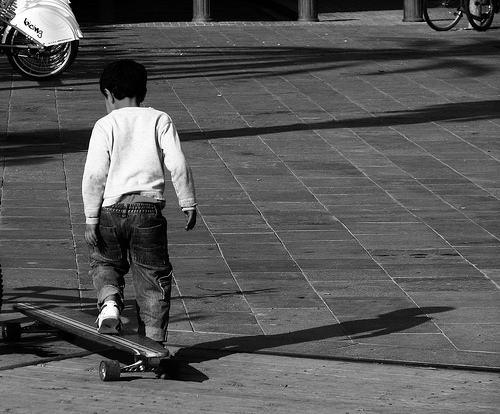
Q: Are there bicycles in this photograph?
A: Yes, there is a bicycle.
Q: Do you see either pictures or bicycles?
A: Yes, there is a bicycle.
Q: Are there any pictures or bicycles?
A: Yes, there is a bicycle.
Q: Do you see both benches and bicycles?
A: No, there is a bicycle but no benches.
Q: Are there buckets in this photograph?
A: No, there are no buckets.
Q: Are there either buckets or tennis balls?
A: No, there are no buckets or tennis balls.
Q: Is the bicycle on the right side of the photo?
A: Yes, the bicycle is on the right of the image.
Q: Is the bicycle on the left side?
A: No, the bicycle is on the right of the image.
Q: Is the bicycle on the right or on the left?
A: The bicycle is on the right of the image.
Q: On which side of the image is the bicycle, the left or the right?
A: The bicycle is on the right of the image.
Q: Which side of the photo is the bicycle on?
A: The bicycle is on the right of the image.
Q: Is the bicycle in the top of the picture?
A: Yes, the bicycle is in the top of the image.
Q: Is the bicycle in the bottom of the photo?
A: No, the bicycle is in the top of the image.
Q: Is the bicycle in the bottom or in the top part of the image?
A: The bicycle is in the top of the image.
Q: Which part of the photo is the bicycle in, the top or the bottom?
A: The bicycle is in the top of the image.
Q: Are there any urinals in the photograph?
A: No, there are no urinals.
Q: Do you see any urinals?
A: No, there are no urinals.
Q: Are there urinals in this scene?
A: No, there are no urinals.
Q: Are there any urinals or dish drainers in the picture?
A: No, there are no urinals or dish drainers.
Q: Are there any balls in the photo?
A: No, there are no balls.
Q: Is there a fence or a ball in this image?
A: No, there are no balls or fences.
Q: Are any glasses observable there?
A: No, there are no glasses.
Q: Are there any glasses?
A: No, there are no glasses.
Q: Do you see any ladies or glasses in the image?
A: No, there are no glasses or ladies.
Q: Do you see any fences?
A: No, there are no fences.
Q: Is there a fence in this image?
A: No, there are no fences.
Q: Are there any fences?
A: No, there are no fences.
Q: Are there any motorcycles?
A: Yes, there is a motorcycle.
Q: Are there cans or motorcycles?
A: Yes, there is a motorcycle.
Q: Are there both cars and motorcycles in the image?
A: No, there is a motorcycle but no cars.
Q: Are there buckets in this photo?
A: No, there are no buckets.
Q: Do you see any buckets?
A: No, there are no buckets.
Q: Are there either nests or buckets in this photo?
A: No, there are no buckets or nests.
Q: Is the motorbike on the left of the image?
A: Yes, the motorbike is on the left of the image.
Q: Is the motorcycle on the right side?
A: No, the motorcycle is on the left of the image.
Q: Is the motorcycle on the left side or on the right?
A: The motorcycle is on the left of the image.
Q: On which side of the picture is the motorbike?
A: The motorbike is on the left of the image.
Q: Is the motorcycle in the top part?
A: Yes, the motorcycle is in the top of the image.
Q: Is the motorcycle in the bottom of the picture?
A: No, the motorcycle is in the top of the image.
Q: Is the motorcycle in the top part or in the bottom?
A: The motorcycle is in the top of the image.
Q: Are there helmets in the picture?
A: No, there are no helmets.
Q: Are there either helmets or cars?
A: No, there are no helmets or cars.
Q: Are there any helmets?
A: No, there are no helmets.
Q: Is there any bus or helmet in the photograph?
A: No, there are no helmets or buses.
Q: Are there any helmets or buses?
A: No, there are no helmets or buses.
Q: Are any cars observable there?
A: No, there are no cars.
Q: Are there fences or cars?
A: No, there are no cars or fences.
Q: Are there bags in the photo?
A: No, there are no bags.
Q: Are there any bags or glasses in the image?
A: No, there are no bags or glasses.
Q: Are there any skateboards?
A: Yes, there is a skateboard.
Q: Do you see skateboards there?
A: Yes, there is a skateboard.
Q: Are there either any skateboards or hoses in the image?
A: Yes, there is a skateboard.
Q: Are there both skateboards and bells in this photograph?
A: No, there is a skateboard but no bells.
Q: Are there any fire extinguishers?
A: No, there are no fire extinguishers.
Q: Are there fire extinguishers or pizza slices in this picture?
A: No, there are no fire extinguishers or pizza slices.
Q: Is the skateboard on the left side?
A: Yes, the skateboard is on the left of the image.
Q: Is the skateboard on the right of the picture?
A: No, the skateboard is on the left of the image.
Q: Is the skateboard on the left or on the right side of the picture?
A: The skateboard is on the left of the image.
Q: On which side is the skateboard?
A: The skateboard is on the left of the image.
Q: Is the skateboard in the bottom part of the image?
A: Yes, the skateboard is in the bottom of the image.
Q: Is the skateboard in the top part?
A: No, the skateboard is in the bottom of the image.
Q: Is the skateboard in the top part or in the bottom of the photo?
A: The skateboard is in the bottom of the image.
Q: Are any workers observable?
A: No, there are no workers.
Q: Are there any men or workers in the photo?
A: No, there are no workers or men.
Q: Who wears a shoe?
A: The boy wears a shoe.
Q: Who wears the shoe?
A: The boy wears a shoe.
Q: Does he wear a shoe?
A: Yes, the boy wears a shoe.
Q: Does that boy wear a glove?
A: No, the boy wears a shoe.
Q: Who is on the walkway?
A: The boy is on the walkway.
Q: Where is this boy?
A: The boy is on the walkway.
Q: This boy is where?
A: The boy is on the walkway.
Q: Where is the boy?
A: The boy is on the walkway.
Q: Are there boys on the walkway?
A: Yes, there is a boy on the walkway.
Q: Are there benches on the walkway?
A: No, there is a boy on the walkway.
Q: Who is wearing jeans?
A: The boy is wearing jeans.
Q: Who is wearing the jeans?
A: The boy is wearing jeans.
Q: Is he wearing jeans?
A: Yes, the boy is wearing jeans.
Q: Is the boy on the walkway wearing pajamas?
A: No, the boy is wearing jeans.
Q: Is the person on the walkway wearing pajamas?
A: No, the boy is wearing jeans.